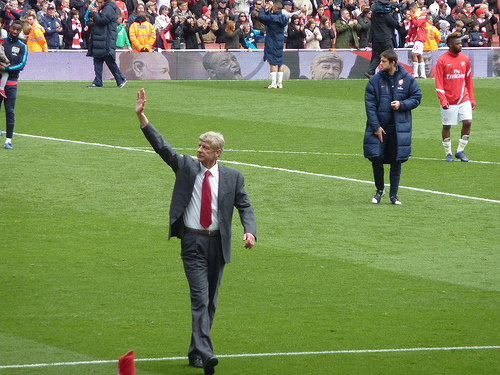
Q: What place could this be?
A: It is a field.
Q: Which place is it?
A: It is a field.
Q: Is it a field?
A: Yes, it is a field.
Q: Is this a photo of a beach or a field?
A: It is showing a field.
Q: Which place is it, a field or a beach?
A: It is a field.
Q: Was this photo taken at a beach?
A: No, the picture was taken in a field.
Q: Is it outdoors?
A: Yes, it is outdoors.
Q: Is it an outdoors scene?
A: Yes, it is outdoors.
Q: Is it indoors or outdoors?
A: It is outdoors.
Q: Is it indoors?
A: No, it is outdoors.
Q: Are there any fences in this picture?
A: No, there are no fences.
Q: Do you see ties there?
A: Yes, there is a tie.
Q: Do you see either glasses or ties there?
A: Yes, there is a tie.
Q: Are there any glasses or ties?
A: Yes, there is a tie.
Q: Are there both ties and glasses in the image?
A: No, there is a tie but no glasses.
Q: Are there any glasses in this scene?
A: No, there are no glasses.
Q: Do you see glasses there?
A: No, there are no glasses.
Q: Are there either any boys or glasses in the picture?
A: No, there are no glasses or boys.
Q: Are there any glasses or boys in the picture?
A: No, there are no glasses or boys.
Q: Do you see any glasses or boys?
A: No, there are no glasses or boys.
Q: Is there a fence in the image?
A: No, there are no fences.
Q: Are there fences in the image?
A: No, there are no fences.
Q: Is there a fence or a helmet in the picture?
A: No, there are no fences or helmets.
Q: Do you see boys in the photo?
A: No, there are no boys.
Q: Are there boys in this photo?
A: No, there are no boys.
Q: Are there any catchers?
A: No, there are no catchers.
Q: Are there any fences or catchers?
A: No, there are no catchers or fences.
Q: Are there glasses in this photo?
A: No, there are no glasses.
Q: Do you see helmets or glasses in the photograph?
A: No, there are no glasses or helmets.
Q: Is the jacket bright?
A: Yes, the jacket is bright.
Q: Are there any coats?
A: Yes, there is a coat.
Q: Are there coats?
A: Yes, there is a coat.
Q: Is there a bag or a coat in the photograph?
A: Yes, there is a coat.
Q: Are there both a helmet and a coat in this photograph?
A: No, there is a coat but no helmets.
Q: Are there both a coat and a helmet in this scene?
A: No, there is a coat but no helmets.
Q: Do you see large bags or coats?
A: Yes, there is a large coat.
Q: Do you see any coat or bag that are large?
A: Yes, the coat is large.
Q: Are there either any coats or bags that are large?
A: Yes, the coat is large.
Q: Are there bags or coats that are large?
A: Yes, the coat is large.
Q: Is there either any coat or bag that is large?
A: Yes, the coat is large.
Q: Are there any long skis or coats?
A: Yes, there is a long coat.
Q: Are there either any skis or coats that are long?
A: Yes, the coat is long.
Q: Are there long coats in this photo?
A: Yes, there is a long coat.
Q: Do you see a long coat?
A: Yes, there is a long coat.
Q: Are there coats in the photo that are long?
A: Yes, there is a coat that is long.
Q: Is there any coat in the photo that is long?
A: Yes, there is a coat that is long.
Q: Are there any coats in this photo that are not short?
A: Yes, there is a long coat.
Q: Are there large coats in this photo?
A: Yes, there is a large coat.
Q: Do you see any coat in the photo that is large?
A: Yes, there is a coat that is large.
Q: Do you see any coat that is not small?
A: Yes, there is a large coat.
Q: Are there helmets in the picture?
A: No, there are no helmets.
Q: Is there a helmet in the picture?
A: No, there are no helmets.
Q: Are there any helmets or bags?
A: No, there are no helmets or bags.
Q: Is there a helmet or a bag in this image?
A: No, there are no helmets or bags.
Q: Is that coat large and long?
A: Yes, the coat is large and long.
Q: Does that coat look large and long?
A: Yes, the coat is large and long.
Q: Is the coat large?
A: Yes, the coat is large.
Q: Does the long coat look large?
A: Yes, the coat is large.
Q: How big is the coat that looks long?
A: The coat is large.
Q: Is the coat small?
A: No, the coat is large.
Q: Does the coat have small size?
A: No, the coat is large.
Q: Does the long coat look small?
A: No, the coat is large.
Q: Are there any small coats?
A: No, there is a coat but it is large.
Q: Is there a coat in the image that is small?
A: No, there is a coat but it is large.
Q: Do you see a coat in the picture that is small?
A: No, there is a coat but it is large.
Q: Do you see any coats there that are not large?
A: No, there is a coat but it is large.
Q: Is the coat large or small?
A: The coat is large.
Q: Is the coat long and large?
A: Yes, the coat is long and large.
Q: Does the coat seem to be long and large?
A: Yes, the coat is long and large.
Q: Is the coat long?
A: Yes, the coat is long.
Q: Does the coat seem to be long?
A: Yes, the coat is long.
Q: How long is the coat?
A: The coat is long.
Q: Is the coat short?
A: No, the coat is long.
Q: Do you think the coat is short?
A: No, the coat is long.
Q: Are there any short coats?
A: No, there is a coat but it is long.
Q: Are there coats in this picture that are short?
A: No, there is a coat but it is long.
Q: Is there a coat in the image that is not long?
A: No, there is a coat but it is long.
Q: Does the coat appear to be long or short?
A: The coat is long.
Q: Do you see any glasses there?
A: No, there are no glasses.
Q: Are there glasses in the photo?
A: No, there are no glasses.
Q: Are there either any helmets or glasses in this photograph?
A: No, there are no glasses or helmets.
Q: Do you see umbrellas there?
A: No, there are no umbrellas.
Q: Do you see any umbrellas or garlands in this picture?
A: No, there are no umbrellas or garlands.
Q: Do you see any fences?
A: No, there are no fences.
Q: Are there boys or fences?
A: No, there are no fences or boys.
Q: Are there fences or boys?
A: No, there are no fences or boys.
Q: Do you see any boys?
A: No, there are no boys.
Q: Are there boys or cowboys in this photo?
A: No, there are no boys or cowboys.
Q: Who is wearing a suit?
A: The man is wearing a suit.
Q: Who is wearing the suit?
A: The man is wearing a suit.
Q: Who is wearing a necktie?
A: The man is wearing a necktie.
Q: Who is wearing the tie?
A: The man is wearing a necktie.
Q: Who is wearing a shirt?
A: The man is wearing a shirt.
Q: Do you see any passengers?
A: No, there are no passengers.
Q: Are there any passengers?
A: No, there are no passengers.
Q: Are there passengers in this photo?
A: No, there are no passengers.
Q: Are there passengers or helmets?
A: No, there are no passengers or helmets.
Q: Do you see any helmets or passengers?
A: No, there are no passengers or helmets.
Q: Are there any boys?
A: No, there are no boys.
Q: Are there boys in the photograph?
A: No, there are no boys.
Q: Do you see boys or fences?
A: No, there are no boys or fences.